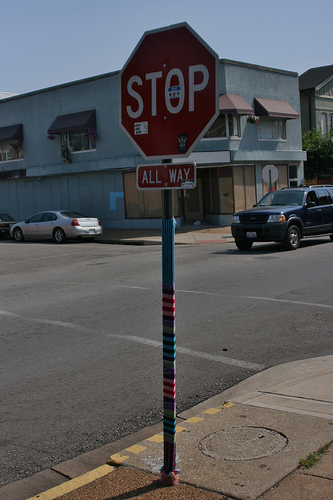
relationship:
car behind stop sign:
[9, 208, 102, 240] [117, 21, 219, 160]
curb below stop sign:
[36, 399, 235, 499] [117, 21, 219, 160]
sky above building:
[0, 1, 333, 98] [0, 59, 301, 225]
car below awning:
[9, 208, 102, 240] [49, 109, 98, 138]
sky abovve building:
[0, 1, 333, 98] [0, 59, 301, 225]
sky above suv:
[0, 1, 333, 98] [231, 184, 333, 258]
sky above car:
[0, 1, 333, 98] [9, 208, 102, 240]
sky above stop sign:
[0, 1, 333, 98] [117, 21, 219, 160]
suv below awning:
[231, 184, 333, 258] [258, 98, 299, 124]